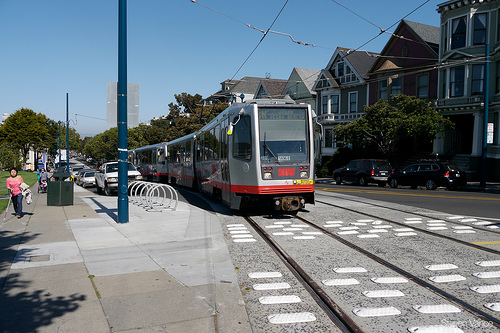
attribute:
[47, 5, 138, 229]
utility poles — blue 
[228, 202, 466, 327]
white rectangles — white 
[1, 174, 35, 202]
pink shirt — pink 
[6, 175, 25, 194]
pink shirt — pink 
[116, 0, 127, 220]
pole — tall , blue 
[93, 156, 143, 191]
white truck — white 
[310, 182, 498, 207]
yellow line — yellow 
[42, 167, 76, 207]
garbage can — large , green 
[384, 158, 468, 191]
black car — black , parked 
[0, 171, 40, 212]
grass — green 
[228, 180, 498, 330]
train tracks — metal 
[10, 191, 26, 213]
blue jeans — blue 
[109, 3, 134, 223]
blue pole — blue 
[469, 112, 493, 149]
pole — blue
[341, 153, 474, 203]
vehicles — black, parked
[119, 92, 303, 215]
train — stopped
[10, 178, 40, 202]
shirt — pink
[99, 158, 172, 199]
truck — white, parked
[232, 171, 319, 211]
bumper — red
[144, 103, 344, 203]
train — commuter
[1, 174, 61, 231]
woman — walking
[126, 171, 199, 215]
rack — empty